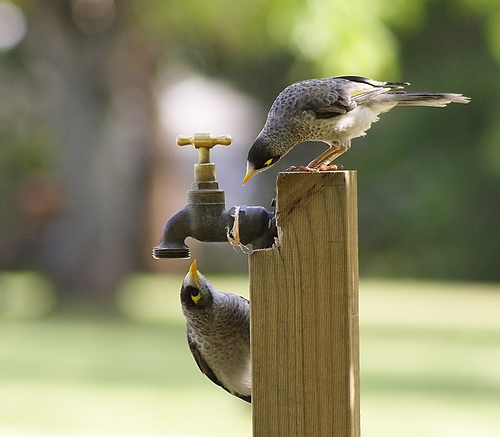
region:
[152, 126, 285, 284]
Black and brass water faucet.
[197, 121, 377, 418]
Wood post holding water faucet.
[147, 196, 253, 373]
Bird waiting for water to drip.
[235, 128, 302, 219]
Orange beak on bird.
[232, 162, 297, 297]
Cut out in wood post.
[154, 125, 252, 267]
Brass handle on faucet.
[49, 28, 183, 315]
Tree in the background.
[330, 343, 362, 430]
Ray of light on wood.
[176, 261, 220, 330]
Yellow eye on the bird.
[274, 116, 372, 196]
Orange feet on bird.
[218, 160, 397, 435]
The post is made of wood.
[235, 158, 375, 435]
The post is brown.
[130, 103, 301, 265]
A tap is on the post.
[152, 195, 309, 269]
The tap is black.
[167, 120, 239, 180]
The handle is gold.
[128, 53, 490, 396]
Two birds are on the post.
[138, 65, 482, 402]
The birds are black and white.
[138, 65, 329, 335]
The birds have yellow beaks.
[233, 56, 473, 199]
One bird is on top of the post.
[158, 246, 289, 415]
One bird is on the side of the post.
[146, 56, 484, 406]
two birds sitting on a water faucet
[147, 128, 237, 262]
water faucet with brass handle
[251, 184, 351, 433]
water faucet with wood housing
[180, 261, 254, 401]
bird looking into water faucet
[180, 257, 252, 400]
gray and white bird with yellow beak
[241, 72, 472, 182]
bird looking down on faucet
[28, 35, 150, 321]
large tree on the grass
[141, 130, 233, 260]
water faucet turned off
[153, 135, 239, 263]
brass spigot turned off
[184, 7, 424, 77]
green tree leaves over the grass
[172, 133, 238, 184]
the handle of the faucet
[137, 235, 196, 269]
the spiket for the faucet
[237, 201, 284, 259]
the water line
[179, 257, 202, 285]
the yellow bird beak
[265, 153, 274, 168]
yellow mark on cheek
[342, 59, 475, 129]
the birds tail feathers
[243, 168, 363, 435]
the wooden post for faucet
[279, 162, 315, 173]
the bird claws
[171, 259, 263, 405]
the bird looking up the water faucet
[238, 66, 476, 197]
a bird on top of the post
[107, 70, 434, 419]
The birds are looking at the faucet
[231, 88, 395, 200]
The bird is looking down toward the ground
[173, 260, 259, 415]
The bird is looking up at the faucet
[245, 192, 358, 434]
The pole holding the faucet is wooden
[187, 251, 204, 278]
The beak is yellow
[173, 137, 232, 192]
The faucet of handle is gold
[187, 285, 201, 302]
The bird has a dark eye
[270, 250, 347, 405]
the wood is grained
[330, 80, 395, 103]
The bird has yellow under its feathers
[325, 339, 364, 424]
The post has light shining on it